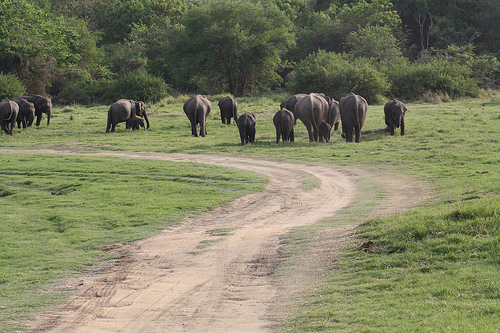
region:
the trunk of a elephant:
[38, 105, 63, 128]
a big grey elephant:
[92, 93, 170, 139]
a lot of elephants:
[99, 76, 408, 161]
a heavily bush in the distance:
[66, 13, 348, 107]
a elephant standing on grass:
[173, 61, 245, 146]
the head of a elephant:
[35, 91, 70, 124]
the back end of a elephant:
[94, 94, 121, 139]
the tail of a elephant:
[346, 102, 370, 130]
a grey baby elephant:
[228, 96, 269, 148]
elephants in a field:
[121, 70, 442, 192]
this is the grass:
[98, 163, 182, 215]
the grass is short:
[98, 182, 164, 209]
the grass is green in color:
[86, 185, 157, 203]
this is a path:
[140, 259, 217, 319]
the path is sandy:
[156, 263, 189, 307]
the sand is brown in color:
[174, 275, 223, 330]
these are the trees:
[35, 0, 381, 81]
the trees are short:
[173, 7, 358, 72]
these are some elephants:
[13, 83, 408, 141]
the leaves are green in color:
[253, 12, 299, 52]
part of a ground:
[232, 216, 260, 271]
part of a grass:
[393, 260, 418, 310]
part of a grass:
[443, 206, 465, 241]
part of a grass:
[426, 200, 473, 262]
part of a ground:
[225, 252, 253, 295]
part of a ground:
[396, 265, 431, 301]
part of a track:
[226, 243, 266, 275]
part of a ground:
[204, 255, 262, 331]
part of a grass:
[396, 220, 442, 283]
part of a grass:
[373, 253, 410, 295]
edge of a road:
[154, 200, 224, 287]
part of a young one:
[120, 118, 141, 138]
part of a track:
[196, 272, 232, 317]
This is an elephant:
[84, 84, 138, 136]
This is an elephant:
[179, 88, 216, 133]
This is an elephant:
[216, 88, 239, 125]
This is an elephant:
[237, 107, 262, 149]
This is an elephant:
[271, 105, 301, 139]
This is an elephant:
[380, 90, 415, 142]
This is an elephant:
[339, 83, 371, 139]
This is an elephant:
[299, 90, 331, 145]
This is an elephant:
[321, 94, 340, 139]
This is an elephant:
[280, 83, 307, 125]